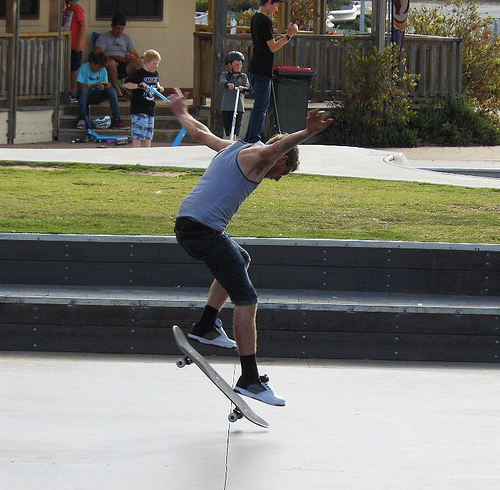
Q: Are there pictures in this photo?
A: No, there are no pictures.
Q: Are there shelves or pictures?
A: No, there are no pictures or shelves.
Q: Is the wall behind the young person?
A: Yes, the wall is behind the person.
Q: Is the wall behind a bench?
A: No, the wall is behind the person.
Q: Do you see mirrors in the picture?
A: No, there are no mirrors.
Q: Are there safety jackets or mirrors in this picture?
A: No, there are no mirrors or safety jackets.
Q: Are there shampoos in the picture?
A: No, there are no shampoos.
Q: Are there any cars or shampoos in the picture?
A: No, there are no shampoos or cars.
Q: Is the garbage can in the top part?
A: Yes, the garbage can is in the top of the image.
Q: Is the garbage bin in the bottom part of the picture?
A: No, the garbage bin is in the top of the image.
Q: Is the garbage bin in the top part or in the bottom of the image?
A: The garbage bin is in the top of the image.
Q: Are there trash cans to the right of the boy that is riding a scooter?
A: Yes, there is a trash can to the right of the boy.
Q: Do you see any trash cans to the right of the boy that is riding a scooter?
A: Yes, there is a trash can to the right of the boy.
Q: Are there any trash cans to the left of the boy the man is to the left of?
A: No, the trash can is to the right of the boy.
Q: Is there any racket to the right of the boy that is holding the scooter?
A: No, there is a trash can to the right of the boy.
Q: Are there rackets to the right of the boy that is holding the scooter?
A: No, there is a trash can to the right of the boy.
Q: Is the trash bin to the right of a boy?
A: Yes, the trash bin is to the right of a boy.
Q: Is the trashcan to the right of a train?
A: No, the trashcan is to the right of a boy.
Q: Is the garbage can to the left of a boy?
A: No, the garbage can is to the right of a boy.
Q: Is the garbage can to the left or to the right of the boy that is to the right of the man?
A: The garbage can is to the right of the boy.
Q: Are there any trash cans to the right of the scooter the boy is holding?
A: Yes, there is a trash can to the right of the scooter.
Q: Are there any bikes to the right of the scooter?
A: No, there is a trash can to the right of the scooter.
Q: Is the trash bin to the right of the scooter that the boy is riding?
A: Yes, the trash bin is to the right of the scooter.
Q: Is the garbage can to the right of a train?
A: No, the garbage can is to the right of the scooter.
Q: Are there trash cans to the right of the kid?
A: Yes, there is a trash can to the right of the kid.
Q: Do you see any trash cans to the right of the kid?
A: Yes, there is a trash can to the right of the kid.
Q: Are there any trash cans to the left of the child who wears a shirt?
A: No, the trash can is to the right of the child.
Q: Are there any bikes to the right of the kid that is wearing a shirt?
A: No, there is a trash can to the right of the kid.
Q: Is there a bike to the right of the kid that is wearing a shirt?
A: No, there is a trash can to the right of the kid.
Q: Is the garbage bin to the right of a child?
A: Yes, the garbage bin is to the right of a child.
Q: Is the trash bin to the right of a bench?
A: No, the trash bin is to the right of a child.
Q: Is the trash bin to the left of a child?
A: No, the trash bin is to the right of a child.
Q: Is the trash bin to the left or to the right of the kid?
A: The trash bin is to the right of the kid.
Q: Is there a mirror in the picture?
A: No, there are no mirrors.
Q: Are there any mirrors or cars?
A: No, there are no mirrors or cars.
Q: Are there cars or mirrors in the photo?
A: No, there are no mirrors or cars.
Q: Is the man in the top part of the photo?
A: Yes, the man is in the top of the image.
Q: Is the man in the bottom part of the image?
A: No, the man is in the top of the image.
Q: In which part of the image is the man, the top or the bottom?
A: The man is in the top of the image.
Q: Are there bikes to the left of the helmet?
A: No, there is a man to the left of the helmet.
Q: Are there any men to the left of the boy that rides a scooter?
A: Yes, there is a man to the left of the boy.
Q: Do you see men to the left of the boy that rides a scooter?
A: Yes, there is a man to the left of the boy.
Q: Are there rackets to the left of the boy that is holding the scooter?
A: No, there is a man to the left of the boy.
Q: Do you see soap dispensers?
A: No, there are no soap dispensers.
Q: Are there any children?
A: Yes, there is a child.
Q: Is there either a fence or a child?
A: Yes, there is a child.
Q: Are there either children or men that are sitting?
A: Yes, the child is sitting.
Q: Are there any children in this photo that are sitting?
A: Yes, there is a child that is sitting.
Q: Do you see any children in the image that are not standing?
A: Yes, there is a child that is sitting .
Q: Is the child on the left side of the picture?
A: Yes, the child is on the left of the image.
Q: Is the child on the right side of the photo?
A: No, the child is on the left of the image.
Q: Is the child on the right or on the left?
A: The child is on the left of the image.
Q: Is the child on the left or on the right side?
A: The child is on the left of the image.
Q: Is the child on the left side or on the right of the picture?
A: The child is on the left of the image.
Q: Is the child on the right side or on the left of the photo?
A: The child is on the left of the image.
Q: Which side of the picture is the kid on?
A: The kid is on the left of the image.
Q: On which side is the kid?
A: The kid is on the left of the image.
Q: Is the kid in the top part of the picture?
A: Yes, the kid is in the top of the image.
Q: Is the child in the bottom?
A: No, the child is in the top of the image.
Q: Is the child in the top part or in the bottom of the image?
A: The child is in the top of the image.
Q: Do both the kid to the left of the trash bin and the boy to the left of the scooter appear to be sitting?
A: Yes, both the child and the boy are sitting.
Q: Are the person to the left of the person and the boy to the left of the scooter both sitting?
A: Yes, both the child and the boy are sitting.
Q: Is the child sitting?
A: Yes, the child is sitting.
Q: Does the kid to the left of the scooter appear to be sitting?
A: Yes, the kid is sitting.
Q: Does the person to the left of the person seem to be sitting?
A: Yes, the kid is sitting.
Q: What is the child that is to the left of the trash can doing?
A: The kid is sitting.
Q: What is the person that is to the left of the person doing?
A: The kid is sitting.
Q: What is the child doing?
A: The kid is sitting.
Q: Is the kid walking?
A: No, the kid is sitting.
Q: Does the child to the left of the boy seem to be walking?
A: No, the child is sitting.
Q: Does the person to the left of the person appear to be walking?
A: No, the child is sitting.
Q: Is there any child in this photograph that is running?
A: No, there is a child but he is sitting.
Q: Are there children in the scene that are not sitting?
A: No, there is a child but he is sitting.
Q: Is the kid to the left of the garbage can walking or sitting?
A: The kid is sitting.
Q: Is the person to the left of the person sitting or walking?
A: The kid is sitting.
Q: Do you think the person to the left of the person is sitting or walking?
A: The kid is sitting.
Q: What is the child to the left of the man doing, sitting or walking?
A: The kid is sitting.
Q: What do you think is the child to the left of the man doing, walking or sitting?
A: The kid is sitting.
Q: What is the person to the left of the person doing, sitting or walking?
A: The kid is sitting.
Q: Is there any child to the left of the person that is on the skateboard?
A: Yes, there is a child to the left of the person.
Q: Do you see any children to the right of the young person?
A: No, the child is to the left of the person.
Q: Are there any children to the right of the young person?
A: No, the child is to the left of the person.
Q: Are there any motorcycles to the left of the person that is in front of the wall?
A: No, there is a child to the left of the person.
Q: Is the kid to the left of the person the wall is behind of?
A: Yes, the kid is to the left of the person.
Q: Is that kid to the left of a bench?
A: No, the kid is to the left of the person.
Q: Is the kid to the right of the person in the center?
A: No, the kid is to the left of the person.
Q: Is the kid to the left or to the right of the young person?
A: The kid is to the left of the person.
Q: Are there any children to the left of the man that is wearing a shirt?
A: Yes, there is a child to the left of the man.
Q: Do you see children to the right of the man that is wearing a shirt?
A: No, the child is to the left of the man.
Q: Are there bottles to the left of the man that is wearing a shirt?
A: No, there is a child to the left of the man.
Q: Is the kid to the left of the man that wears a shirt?
A: Yes, the kid is to the left of the man.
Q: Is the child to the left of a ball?
A: No, the child is to the left of the man.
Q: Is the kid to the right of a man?
A: No, the kid is to the left of a man.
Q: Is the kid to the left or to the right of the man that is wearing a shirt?
A: The kid is to the left of the man.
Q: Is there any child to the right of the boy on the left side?
A: Yes, there is a child to the right of the boy.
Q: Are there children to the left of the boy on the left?
A: No, the child is to the right of the boy.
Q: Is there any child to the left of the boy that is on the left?
A: No, the child is to the right of the boy.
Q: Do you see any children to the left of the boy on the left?
A: No, the child is to the right of the boy.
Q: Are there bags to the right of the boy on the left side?
A: No, there is a child to the right of the boy.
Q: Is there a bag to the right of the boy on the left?
A: No, there is a child to the right of the boy.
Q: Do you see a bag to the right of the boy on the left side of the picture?
A: No, there is a child to the right of the boy.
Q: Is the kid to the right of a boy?
A: Yes, the kid is to the right of a boy.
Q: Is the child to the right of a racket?
A: No, the child is to the right of a boy.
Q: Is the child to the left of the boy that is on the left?
A: No, the child is to the right of the boy.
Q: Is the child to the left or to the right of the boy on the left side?
A: The child is to the right of the boy.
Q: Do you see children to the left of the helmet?
A: Yes, there is a child to the left of the helmet.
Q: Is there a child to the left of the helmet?
A: Yes, there is a child to the left of the helmet.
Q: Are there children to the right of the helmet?
A: No, the child is to the left of the helmet.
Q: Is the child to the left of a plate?
A: No, the child is to the left of the helmet.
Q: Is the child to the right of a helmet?
A: No, the child is to the left of a helmet.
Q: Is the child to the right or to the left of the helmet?
A: The child is to the left of the helmet.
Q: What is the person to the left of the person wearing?
A: The child is wearing a shirt.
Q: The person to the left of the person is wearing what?
A: The child is wearing a shirt.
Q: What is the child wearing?
A: The child is wearing a shirt.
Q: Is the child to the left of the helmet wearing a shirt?
A: Yes, the kid is wearing a shirt.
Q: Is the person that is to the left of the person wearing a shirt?
A: Yes, the kid is wearing a shirt.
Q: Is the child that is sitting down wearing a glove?
A: No, the child is wearing a shirt.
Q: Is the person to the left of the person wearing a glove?
A: No, the child is wearing a shirt.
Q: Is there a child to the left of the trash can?
A: Yes, there is a child to the left of the trash can.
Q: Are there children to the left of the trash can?
A: Yes, there is a child to the left of the trash can.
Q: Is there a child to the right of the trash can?
A: No, the child is to the left of the trash can.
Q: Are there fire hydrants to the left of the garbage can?
A: No, there is a child to the left of the garbage can.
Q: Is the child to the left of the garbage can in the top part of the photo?
A: Yes, the child is to the left of the trash can.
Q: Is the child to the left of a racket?
A: No, the child is to the left of the trash can.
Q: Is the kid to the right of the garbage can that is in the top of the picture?
A: No, the kid is to the left of the trash bin.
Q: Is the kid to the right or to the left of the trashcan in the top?
A: The kid is to the left of the trash can.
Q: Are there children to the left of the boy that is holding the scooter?
A: Yes, there is a child to the left of the boy.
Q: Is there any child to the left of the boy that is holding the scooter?
A: Yes, there is a child to the left of the boy.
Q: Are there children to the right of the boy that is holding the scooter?
A: No, the child is to the left of the boy.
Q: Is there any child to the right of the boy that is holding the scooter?
A: No, the child is to the left of the boy.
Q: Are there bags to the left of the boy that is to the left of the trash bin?
A: No, there is a child to the left of the boy.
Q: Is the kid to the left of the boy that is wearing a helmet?
A: Yes, the kid is to the left of the boy.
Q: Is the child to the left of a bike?
A: No, the child is to the left of the boy.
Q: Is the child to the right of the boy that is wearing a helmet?
A: No, the child is to the left of the boy.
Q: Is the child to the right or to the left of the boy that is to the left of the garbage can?
A: The child is to the left of the boy.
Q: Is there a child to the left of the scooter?
A: Yes, there is a child to the left of the scooter.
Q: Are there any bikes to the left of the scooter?
A: No, there is a child to the left of the scooter.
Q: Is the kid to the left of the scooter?
A: Yes, the kid is to the left of the scooter.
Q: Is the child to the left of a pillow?
A: No, the child is to the left of the scooter.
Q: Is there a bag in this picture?
A: No, there are no bags.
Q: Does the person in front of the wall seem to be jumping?
A: Yes, the person is jumping.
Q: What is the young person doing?
A: The person is jumping.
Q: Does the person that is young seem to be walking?
A: No, the person is jumping.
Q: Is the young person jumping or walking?
A: The person is jumping.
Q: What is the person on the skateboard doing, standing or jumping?
A: The person is jumping.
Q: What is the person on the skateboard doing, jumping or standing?
A: The person is jumping.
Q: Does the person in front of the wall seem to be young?
A: Yes, the person is young.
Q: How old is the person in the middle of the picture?
A: The person is young.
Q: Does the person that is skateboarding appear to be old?
A: No, the person is young.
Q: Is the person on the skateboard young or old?
A: The person is young.